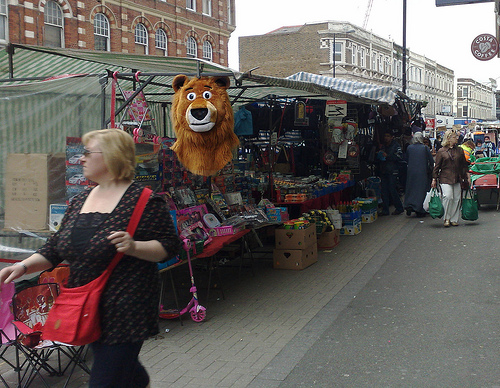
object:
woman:
[0, 125, 186, 384]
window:
[91, 3, 116, 51]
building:
[0, 0, 235, 66]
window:
[131, 12, 153, 57]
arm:
[134, 203, 187, 264]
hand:
[0, 261, 31, 285]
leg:
[92, 321, 149, 383]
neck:
[85, 174, 134, 189]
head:
[441, 127, 464, 147]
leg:
[440, 177, 454, 221]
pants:
[88, 341, 151, 386]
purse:
[40, 185, 153, 348]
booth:
[106, 71, 290, 324]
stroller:
[109, 69, 178, 152]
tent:
[0, 38, 391, 298]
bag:
[426, 186, 444, 217]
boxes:
[272, 222, 320, 252]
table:
[260, 165, 359, 208]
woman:
[400, 129, 434, 217]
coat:
[402, 139, 434, 215]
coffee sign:
[469, 31, 500, 62]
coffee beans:
[480, 40, 484, 55]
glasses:
[79, 148, 104, 157]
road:
[272, 210, 500, 387]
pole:
[400, 0, 409, 95]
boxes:
[271, 244, 321, 273]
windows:
[350, 40, 359, 69]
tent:
[281, 70, 428, 201]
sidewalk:
[0, 207, 423, 386]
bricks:
[149, 348, 178, 366]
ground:
[0, 211, 500, 386]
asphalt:
[277, 205, 500, 385]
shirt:
[68, 209, 112, 257]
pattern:
[118, 209, 128, 220]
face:
[80, 140, 105, 177]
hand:
[105, 231, 136, 255]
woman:
[429, 129, 476, 230]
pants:
[441, 185, 466, 224]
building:
[238, 21, 455, 124]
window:
[329, 37, 346, 67]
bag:
[459, 188, 482, 221]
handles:
[462, 188, 476, 199]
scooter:
[158, 217, 208, 322]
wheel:
[189, 304, 209, 323]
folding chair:
[11, 278, 62, 387]